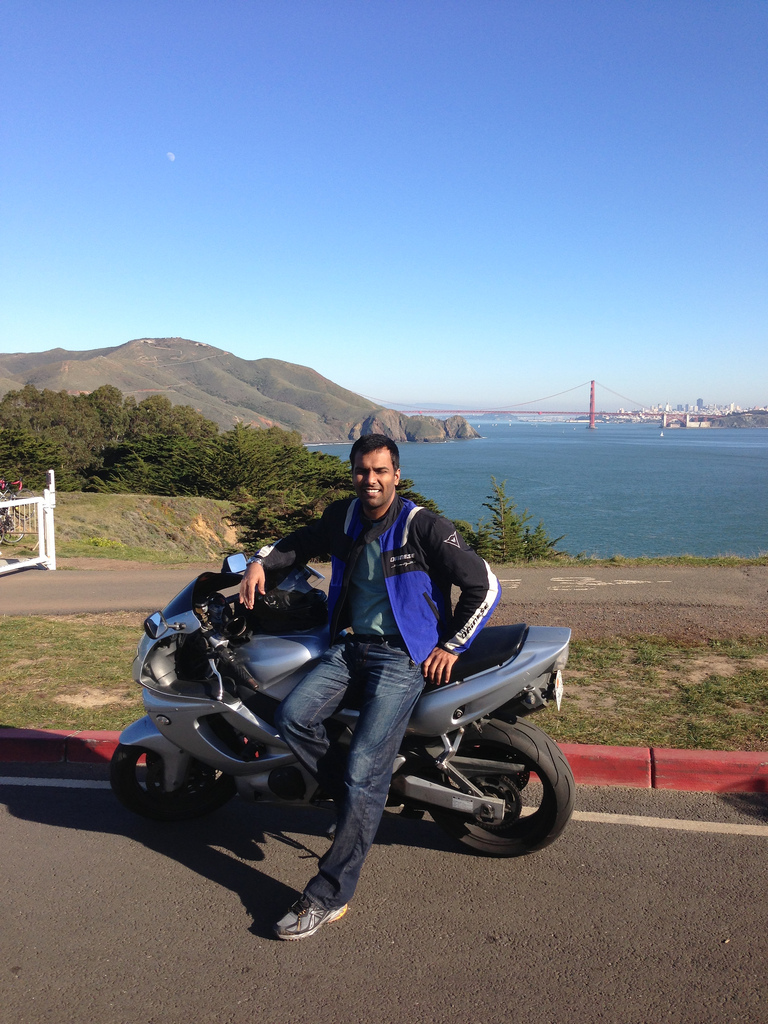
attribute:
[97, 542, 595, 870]
bike — silver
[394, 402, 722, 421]
bridge — San Francisco Bridge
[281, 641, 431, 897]
jeans — blue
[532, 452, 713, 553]
bay — blue, calm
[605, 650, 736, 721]
grass — patchy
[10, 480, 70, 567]
fence — white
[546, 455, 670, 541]
water — large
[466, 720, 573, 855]
wheel — black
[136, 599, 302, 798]
bike — silver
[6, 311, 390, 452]
hills — background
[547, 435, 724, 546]
bay — San Francisco Bay, blue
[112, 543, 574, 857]
crotch rocket — silver, black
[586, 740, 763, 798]
curb — painted , red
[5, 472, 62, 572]
gate — white 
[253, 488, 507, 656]
jacket — blue, black, white